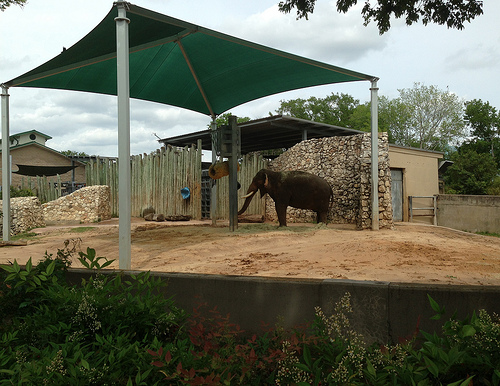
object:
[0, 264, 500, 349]
brickwall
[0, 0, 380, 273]
canopy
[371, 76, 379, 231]
metal pole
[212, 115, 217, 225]
metal pole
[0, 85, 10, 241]
metal pole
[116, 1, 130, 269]
metal pole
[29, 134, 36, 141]
window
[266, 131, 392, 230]
walls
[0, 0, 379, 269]
awning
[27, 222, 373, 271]
shading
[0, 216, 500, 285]
ground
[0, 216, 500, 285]
dirt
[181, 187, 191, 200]
bucket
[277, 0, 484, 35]
tree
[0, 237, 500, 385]
shrubbery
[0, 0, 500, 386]
background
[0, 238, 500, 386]
bush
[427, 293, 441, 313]
leaf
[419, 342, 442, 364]
leaf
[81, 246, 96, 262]
leaf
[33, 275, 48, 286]
leaf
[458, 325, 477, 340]
leaf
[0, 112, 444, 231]
building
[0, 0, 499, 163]
sky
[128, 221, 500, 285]
sand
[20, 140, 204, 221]
fence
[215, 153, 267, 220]
fence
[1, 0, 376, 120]
tent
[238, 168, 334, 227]
elephant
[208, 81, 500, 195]
tree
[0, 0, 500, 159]
cloud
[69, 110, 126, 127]
cloud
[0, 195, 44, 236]
wall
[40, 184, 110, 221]
wall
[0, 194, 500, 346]
enclosure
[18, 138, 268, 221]
tree limb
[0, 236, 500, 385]
planter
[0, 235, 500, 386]
shrub